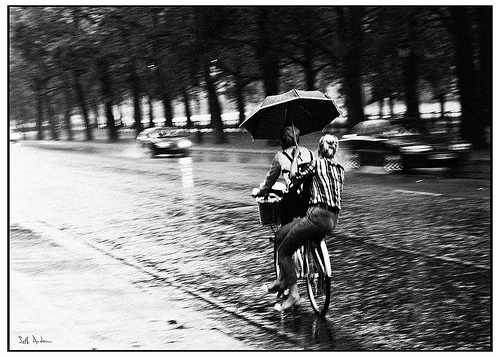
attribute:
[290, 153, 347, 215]
shirt — plaid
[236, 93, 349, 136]
umbrella — dark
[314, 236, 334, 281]
fender — shiny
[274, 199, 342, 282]
pants — dark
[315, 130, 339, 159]
hair — blonde